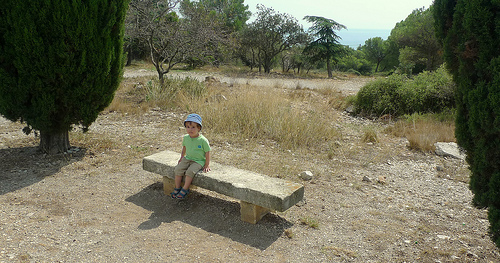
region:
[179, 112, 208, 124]
a little person wearing a blue hat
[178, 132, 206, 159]
a little person wearing a green shirt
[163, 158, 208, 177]
a little person wearing khaki shorts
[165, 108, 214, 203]
a little person sitting on a park bench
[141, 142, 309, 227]
a wooden park bench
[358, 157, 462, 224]
rocks on the ground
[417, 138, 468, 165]
a large white rock next to tree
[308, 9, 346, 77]
a green evergreen tree in the background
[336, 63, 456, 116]
a bunch of green shrubs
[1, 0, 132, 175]
a large green shrub tree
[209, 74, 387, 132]
The weeds are dead.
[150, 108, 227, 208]
The boy is young.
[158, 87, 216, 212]
The boy has a blue hat.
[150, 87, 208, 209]
The boy has a green shirt.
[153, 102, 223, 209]
The boy has tan pants.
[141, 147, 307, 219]
The bench is long.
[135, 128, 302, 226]
The bench is stone.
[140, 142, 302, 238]
The bench is tan.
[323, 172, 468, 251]
The terrain is rocky.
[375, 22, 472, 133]
The trees are leafy.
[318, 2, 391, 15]
The sky is white.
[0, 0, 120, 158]
The tree is green.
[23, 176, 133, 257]
The ground is dirt.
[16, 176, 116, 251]
The dirt is brown.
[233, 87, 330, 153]
The grass is dry.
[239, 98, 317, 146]
The grass is brown.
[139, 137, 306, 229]
The bench is made of stone.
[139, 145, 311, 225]
The bench is off white.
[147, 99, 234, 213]
Someone is sitting on the bench.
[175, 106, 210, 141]
The person is wearing a blue hat.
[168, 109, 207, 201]
little boy with a blue cap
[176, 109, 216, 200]
little boy with green shirt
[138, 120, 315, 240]
little boy sitting on bench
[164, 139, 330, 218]
tan stone bench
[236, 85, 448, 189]
tan dry grass and rocks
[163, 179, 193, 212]
blue sandals on child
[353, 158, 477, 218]
gray gravel and dirt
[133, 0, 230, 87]
tree with no leaves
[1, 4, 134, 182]
a green tree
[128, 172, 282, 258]
shadow of bench and boy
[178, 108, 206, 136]
the head of a person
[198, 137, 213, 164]
the arm of a person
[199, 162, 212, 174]
the hand of a person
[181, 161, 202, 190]
the leg of a person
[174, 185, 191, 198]
the foot of a person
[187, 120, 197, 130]
the eye of a person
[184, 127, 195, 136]
the mouth of a person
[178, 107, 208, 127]
a blue hat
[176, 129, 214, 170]
a green shirt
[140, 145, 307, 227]
a gray cement bench